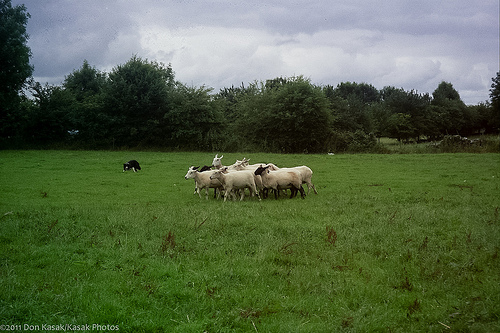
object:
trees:
[365, 85, 455, 148]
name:
[1, 322, 119, 333]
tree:
[98, 55, 177, 153]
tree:
[325, 82, 380, 157]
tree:
[171, 83, 237, 150]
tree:
[210, 79, 255, 146]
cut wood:
[430, 135, 479, 147]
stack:
[428, 132, 484, 151]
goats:
[199, 165, 215, 173]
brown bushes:
[159, 227, 177, 254]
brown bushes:
[326, 225, 338, 246]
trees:
[28, 56, 110, 150]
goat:
[184, 166, 226, 200]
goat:
[254, 162, 306, 200]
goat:
[209, 167, 262, 202]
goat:
[211, 153, 230, 169]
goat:
[227, 160, 257, 172]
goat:
[242, 157, 267, 168]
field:
[0, 209, 500, 333]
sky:
[0, 1, 495, 108]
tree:
[220, 73, 335, 154]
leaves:
[0, 0, 39, 79]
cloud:
[0, 0, 500, 82]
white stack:
[327, 149, 336, 156]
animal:
[121, 160, 142, 172]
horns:
[214, 153, 224, 159]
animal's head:
[211, 153, 224, 166]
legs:
[194, 182, 318, 203]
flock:
[182, 152, 319, 202]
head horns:
[189, 166, 198, 172]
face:
[254, 166, 266, 175]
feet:
[123, 165, 130, 170]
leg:
[306, 177, 318, 194]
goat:
[266, 162, 318, 194]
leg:
[223, 187, 233, 201]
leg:
[250, 185, 262, 202]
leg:
[238, 189, 245, 201]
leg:
[229, 187, 237, 199]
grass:
[0, 147, 500, 333]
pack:
[183, 153, 318, 203]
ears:
[218, 155, 224, 160]